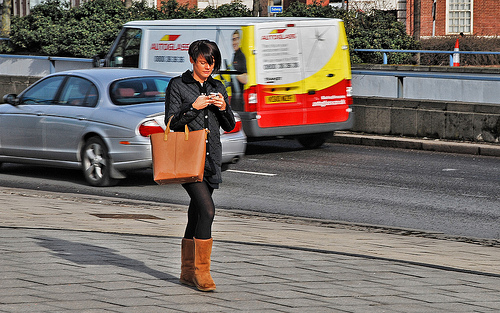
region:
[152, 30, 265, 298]
lady on cell phone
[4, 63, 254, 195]
silver car driving on street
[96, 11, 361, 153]
white yellow red van driving on street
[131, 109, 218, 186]
tan leather purse on arm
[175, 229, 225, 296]
tan boots on lady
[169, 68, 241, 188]
black long coat on lady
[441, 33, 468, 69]
white and orange street cone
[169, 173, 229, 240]
lady's black pants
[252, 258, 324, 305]
tile side street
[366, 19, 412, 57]
bushes with green leafs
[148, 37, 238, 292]
A lady walking on the sidewalk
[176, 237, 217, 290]
A pair of brown boots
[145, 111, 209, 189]
A brown leather handbag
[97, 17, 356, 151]
A yellow, white, and red work van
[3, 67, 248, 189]
A grey car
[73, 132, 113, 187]
The back driver side tire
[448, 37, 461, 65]
An orange and white traffic cone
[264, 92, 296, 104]
The yellow and black licence plate of the van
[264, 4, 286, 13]
A blue and white street sign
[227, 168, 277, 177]
A white line painted on the road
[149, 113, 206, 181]
large brown purse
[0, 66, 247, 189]
silver car on the road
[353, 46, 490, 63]
blue metal fence railing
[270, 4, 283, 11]
blue sign with white letters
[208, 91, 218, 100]
cell phone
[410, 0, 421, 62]
thick wooden power pole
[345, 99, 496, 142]
large gray concrete wall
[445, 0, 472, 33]
window in red building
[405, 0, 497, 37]
red brick building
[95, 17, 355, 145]
white van with picture of a man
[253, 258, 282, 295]
part of a floor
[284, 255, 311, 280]
part of a floor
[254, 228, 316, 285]
part of a floor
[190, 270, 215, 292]
part of a floor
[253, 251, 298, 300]
part of a floor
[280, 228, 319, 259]
part of a floor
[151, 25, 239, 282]
this is a lady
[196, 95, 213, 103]
the lady is light skinned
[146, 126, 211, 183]
this is a bag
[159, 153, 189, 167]
the bag is brown in color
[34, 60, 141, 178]
this is a car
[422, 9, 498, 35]
this is a buildng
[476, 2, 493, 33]
the wall is brown in color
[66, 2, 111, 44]
this is a tree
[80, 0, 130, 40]
the leaves are green in color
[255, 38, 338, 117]
this is a lorry